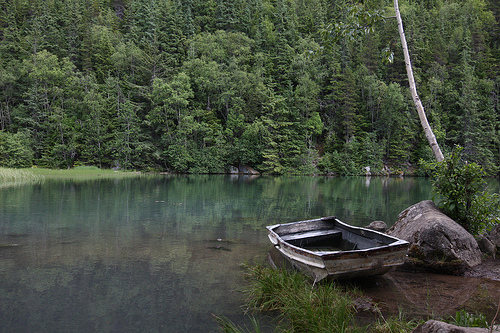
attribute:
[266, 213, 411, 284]
boat — empty, wood, abandoned, little, parked, damaged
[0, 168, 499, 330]
water — shallow, lonely, muddy, reflective, dirty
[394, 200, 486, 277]
rock — big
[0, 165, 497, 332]
river — wide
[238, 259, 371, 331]
grass — tall, green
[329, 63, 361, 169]
tree — green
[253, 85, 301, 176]
tree — green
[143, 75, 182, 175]
tree — green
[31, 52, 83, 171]
tree — green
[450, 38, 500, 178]
tree — green